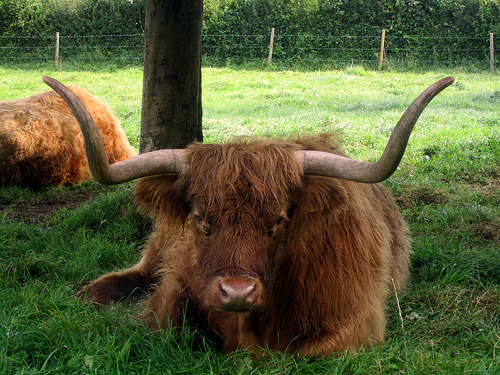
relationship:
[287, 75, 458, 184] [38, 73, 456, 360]
gray horn on animal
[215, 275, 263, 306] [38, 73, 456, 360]
nose on animal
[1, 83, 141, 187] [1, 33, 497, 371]
bull on grass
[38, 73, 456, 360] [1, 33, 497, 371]
animal on grass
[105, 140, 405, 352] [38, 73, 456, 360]
hair on animal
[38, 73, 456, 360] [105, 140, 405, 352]
animal has hair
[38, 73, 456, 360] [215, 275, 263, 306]
animal has nose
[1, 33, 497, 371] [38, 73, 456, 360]
grass behind animal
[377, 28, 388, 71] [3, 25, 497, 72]
post on fence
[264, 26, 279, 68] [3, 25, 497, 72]
post on fence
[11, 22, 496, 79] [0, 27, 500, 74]
wires on fence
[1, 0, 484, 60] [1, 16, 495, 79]
bushes are behind fence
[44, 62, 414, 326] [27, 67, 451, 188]
animal has horns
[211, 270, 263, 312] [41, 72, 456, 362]
nose belongs to animal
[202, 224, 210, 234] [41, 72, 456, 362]
eye belongs to animal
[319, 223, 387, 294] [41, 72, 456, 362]
fur belongs to animal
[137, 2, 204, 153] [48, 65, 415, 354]
tree behind animal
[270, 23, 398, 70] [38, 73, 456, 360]
fence behind animal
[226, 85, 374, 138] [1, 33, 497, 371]
light hitting grass